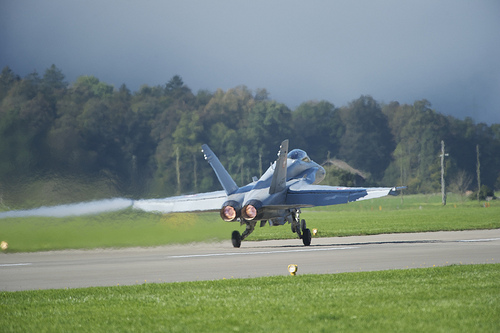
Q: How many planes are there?
A: One.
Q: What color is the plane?
A: White.